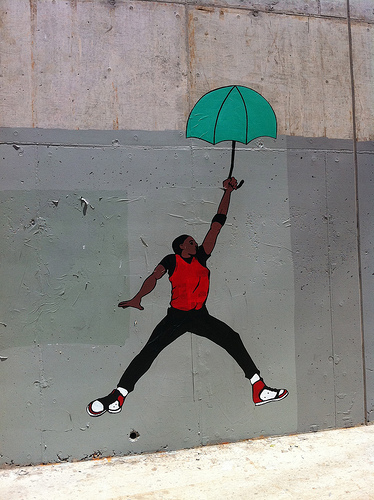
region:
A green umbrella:
[177, 64, 300, 189]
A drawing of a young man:
[153, 226, 221, 324]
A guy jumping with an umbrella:
[87, 72, 292, 421]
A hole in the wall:
[117, 423, 154, 464]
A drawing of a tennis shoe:
[78, 377, 143, 425]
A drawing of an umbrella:
[174, 61, 285, 204]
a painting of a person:
[27, 169, 339, 442]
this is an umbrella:
[167, 67, 297, 179]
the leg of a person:
[197, 318, 319, 445]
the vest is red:
[150, 242, 240, 337]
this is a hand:
[104, 248, 168, 323]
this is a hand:
[176, 168, 242, 252]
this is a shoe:
[64, 379, 133, 429]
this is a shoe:
[244, 362, 295, 409]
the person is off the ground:
[51, 215, 310, 449]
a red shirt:
[171, 260, 208, 305]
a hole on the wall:
[126, 425, 145, 440]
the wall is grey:
[20, 260, 115, 359]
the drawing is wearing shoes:
[86, 392, 125, 416]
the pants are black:
[210, 322, 232, 338]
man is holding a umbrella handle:
[223, 172, 245, 191]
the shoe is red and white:
[247, 379, 291, 403]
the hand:
[113, 296, 146, 313]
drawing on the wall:
[77, 69, 317, 444]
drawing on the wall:
[74, 68, 309, 409]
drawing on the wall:
[73, 70, 301, 448]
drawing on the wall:
[76, 60, 298, 427]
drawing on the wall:
[73, 52, 298, 435]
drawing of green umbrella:
[177, 65, 283, 213]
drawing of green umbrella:
[175, 79, 270, 205]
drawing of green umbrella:
[174, 60, 287, 221]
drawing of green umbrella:
[175, 70, 292, 221]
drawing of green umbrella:
[171, 60, 288, 236]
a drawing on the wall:
[76, 69, 329, 438]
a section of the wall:
[12, 377, 162, 461]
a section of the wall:
[127, 325, 240, 454]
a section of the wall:
[233, 323, 329, 427]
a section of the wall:
[11, 304, 120, 421]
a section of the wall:
[244, 274, 364, 415]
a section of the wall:
[13, 345, 169, 472]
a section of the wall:
[14, 227, 167, 381]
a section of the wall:
[199, 222, 373, 361]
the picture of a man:
[68, 185, 313, 429]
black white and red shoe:
[253, 365, 302, 420]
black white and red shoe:
[79, 369, 141, 425]